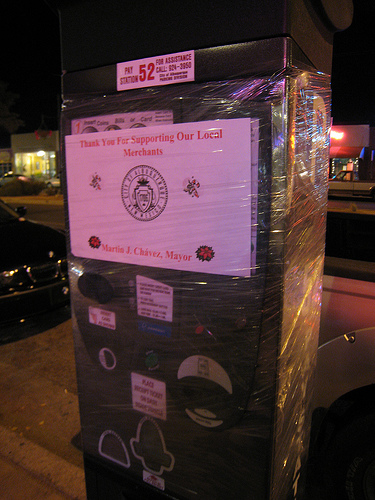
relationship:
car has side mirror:
[0, 184, 71, 336] [17, 206, 28, 218]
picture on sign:
[121, 163, 167, 223] [62, 119, 261, 279]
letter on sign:
[117, 52, 194, 87] [114, 50, 196, 92]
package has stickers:
[56, 3, 333, 498] [67, 262, 240, 492]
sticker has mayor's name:
[62, 119, 261, 279] [98, 242, 192, 268]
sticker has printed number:
[114, 50, 196, 92] [137, 61, 155, 86]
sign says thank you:
[62, 119, 261, 279] [80, 138, 119, 151]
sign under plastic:
[62, 119, 261, 279] [57, 72, 334, 499]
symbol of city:
[119, 167, 166, 224] [135, 183, 153, 211]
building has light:
[8, 122, 369, 193] [328, 126, 348, 147]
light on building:
[328, 126, 348, 147] [8, 122, 369, 193]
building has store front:
[8, 122, 369, 193] [8, 124, 61, 185]